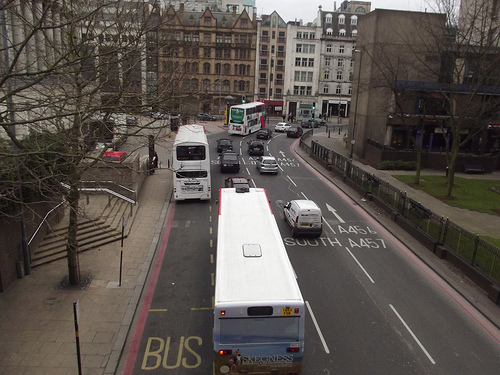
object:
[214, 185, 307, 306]
roof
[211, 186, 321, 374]
bus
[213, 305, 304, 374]
back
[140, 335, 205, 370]
bus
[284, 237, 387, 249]
street name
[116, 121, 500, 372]
street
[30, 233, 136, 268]
steps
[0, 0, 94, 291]
building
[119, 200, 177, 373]
stripe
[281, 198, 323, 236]
van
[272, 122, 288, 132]
car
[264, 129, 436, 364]
line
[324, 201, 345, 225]
arrow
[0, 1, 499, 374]
photo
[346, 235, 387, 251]
numbers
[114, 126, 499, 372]
road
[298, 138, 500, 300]
fence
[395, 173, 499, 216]
grass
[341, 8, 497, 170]
building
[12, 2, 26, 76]
pillars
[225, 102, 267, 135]
bus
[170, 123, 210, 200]
busses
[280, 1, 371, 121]
buildings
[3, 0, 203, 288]
tree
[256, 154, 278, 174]
car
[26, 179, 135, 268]
handrail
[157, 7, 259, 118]
building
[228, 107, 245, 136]
bus back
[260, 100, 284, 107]
awning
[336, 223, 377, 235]
a456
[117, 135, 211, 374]
street lane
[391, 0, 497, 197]
trees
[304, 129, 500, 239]
sidewalk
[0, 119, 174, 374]
sidewalk